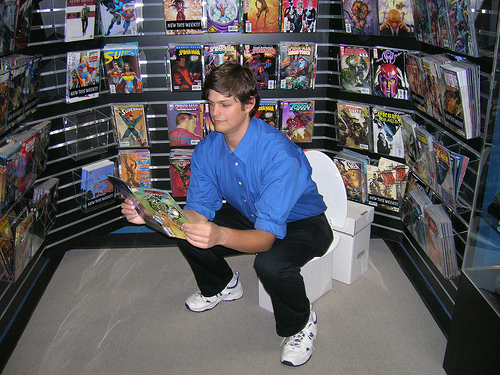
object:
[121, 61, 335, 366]
man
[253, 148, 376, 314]
toilet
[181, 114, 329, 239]
shirt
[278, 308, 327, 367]
sneakers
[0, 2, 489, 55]
racks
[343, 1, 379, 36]
comics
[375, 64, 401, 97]
superheroes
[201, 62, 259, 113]
hair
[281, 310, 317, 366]
foot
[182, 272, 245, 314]
foot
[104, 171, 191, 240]
comic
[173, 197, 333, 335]
pants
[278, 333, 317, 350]
laces